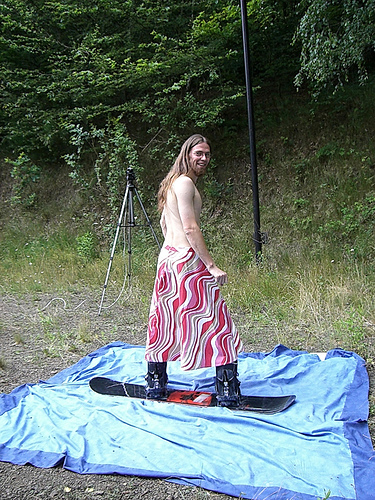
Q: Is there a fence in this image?
A: No, there are no fences.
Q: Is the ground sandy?
A: Yes, the ground is sandy.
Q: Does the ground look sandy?
A: Yes, the ground is sandy.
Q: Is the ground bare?
A: No, the ground is sandy.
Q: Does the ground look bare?
A: No, the ground is sandy.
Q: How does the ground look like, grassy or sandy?
A: The ground is sandy.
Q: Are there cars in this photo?
A: No, there are no cars.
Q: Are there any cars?
A: No, there are no cars.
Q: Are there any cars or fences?
A: No, there are no cars or fences.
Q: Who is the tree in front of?
A: The tree is in front of the man.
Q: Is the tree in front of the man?
A: Yes, the tree is in front of the man.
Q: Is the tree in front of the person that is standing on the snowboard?
A: Yes, the tree is in front of the man.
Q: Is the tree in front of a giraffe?
A: No, the tree is in front of the man.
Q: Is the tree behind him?
A: No, the tree is in front of the man.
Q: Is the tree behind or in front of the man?
A: The tree is in front of the man.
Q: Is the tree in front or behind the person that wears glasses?
A: The tree is in front of the man.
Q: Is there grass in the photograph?
A: Yes, there is grass.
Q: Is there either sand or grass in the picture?
A: Yes, there is grass.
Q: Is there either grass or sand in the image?
A: Yes, there is grass.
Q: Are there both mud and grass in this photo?
A: No, there is grass but no mud.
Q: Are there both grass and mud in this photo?
A: No, there is grass but no mud.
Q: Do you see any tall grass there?
A: Yes, there is tall grass.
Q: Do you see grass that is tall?
A: Yes, there is grass that is tall.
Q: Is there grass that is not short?
A: Yes, there is tall grass.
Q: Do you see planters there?
A: No, there are no planters.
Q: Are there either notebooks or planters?
A: No, there are no planters or notebooks.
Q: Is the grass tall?
A: Yes, the grass is tall.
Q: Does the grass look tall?
A: Yes, the grass is tall.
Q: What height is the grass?
A: The grass is tall.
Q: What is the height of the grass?
A: The grass is tall.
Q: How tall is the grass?
A: The grass is tall.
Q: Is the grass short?
A: No, the grass is tall.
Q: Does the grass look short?
A: No, the grass is tall.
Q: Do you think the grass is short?
A: No, the grass is tall.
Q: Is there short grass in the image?
A: No, there is grass but it is tall.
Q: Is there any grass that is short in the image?
A: No, there is grass but it is tall.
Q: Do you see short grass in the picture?
A: No, there is grass but it is tall.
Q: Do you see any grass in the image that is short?
A: No, there is grass but it is tall.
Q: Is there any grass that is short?
A: No, there is grass but it is tall.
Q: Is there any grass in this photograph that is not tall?
A: No, there is grass but it is tall.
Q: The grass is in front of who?
A: The grass is in front of the man.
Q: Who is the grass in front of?
A: The grass is in front of the man.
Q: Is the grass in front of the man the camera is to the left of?
A: Yes, the grass is in front of the man.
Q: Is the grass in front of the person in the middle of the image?
A: Yes, the grass is in front of the man.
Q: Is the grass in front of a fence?
A: No, the grass is in front of the man.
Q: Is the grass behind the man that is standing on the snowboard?
A: No, the grass is in front of the man.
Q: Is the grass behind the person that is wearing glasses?
A: No, the grass is in front of the man.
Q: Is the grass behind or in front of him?
A: The grass is in front of the man.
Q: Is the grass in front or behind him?
A: The grass is in front of the man.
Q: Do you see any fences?
A: No, there are no fences.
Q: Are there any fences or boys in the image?
A: No, there are no fences or boys.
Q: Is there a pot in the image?
A: No, there are no pots.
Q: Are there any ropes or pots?
A: No, there are no pots or ropes.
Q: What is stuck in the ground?
A: The pole is stuck in the ground.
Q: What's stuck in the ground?
A: The pole is stuck in the ground.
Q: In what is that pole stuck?
A: The pole is stuck in the ground.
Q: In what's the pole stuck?
A: The pole is stuck in the ground.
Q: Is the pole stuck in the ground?
A: Yes, the pole is stuck in the ground.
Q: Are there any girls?
A: No, there are no girls.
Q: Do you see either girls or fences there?
A: No, there are no girls or fences.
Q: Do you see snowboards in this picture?
A: Yes, there is a snowboard.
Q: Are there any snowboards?
A: Yes, there is a snowboard.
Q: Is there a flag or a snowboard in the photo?
A: Yes, there is a snowboard.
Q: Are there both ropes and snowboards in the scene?
A: No, there is a snowboard but no ropes.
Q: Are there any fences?
A: No, there are no fences.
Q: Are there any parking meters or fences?
A: No, there are no fences or parking meters.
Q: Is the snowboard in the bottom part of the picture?
A: Yes, the snowboard is in the bottom of the image.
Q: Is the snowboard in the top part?
A: No, the snowboard is in the bottom of the image.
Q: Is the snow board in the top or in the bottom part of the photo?
A: The snow board is in the bottom of the image.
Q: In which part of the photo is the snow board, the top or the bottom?
A: The snow board is in the bottom of the image.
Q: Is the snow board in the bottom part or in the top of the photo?
A: The snow board is in the bottom of the image.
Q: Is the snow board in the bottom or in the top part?
A: The snow board is in the bottom of the image.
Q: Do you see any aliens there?
A: No, there are no aliens.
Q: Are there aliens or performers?
A: No, there are no aliens or performers.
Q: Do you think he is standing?
A: Yes, the man is standing.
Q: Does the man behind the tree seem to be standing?
A: Yes, the man is standing.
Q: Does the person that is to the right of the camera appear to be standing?
A: Yes, the man is standing.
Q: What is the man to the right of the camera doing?
A: The man is standing.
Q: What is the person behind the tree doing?
A: The man is standing.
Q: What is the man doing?
A: The man is standing.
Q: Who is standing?
A: The man is standing.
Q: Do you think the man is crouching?
A: No, the man is standing.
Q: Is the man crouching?
A: No, the man is standing.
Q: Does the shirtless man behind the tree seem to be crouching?
A: No, the man is standing.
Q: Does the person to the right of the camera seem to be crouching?
A: No, the man is standing.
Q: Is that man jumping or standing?
A: The man is standing.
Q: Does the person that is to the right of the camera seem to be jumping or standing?
A: The man is standing.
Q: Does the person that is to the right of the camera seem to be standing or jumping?
A: The man is standing.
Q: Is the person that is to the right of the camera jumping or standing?
A: The man is standing.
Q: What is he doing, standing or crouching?
A: The man is standing.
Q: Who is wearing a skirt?
A: The man is wearing a skirt.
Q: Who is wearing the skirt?
A: The man is wearing a skirt.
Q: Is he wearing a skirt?
A: Yes, the man is wearing a skirt.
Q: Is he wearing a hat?
A: No, the man is wearing a skirt.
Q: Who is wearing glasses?
A: The man is wearing glasses.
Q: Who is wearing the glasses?
A: The man is wearing glasses.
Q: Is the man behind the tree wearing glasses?
A: Yes, the man is wearing glasses.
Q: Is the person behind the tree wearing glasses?
A: Yes, the man is wearing glasses.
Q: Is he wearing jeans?
A: No, the man is wearing glasses.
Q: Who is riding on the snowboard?
A: The man is riding on the snow board.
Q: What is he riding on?
A: The man is riding on the snow board.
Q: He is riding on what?
A: The man is riding on the snow board.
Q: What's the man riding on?
A: The man is riding on the snow board.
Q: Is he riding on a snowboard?
A: Yes, the man is riding on a snowboard.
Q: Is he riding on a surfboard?
A: No, the man is riding on a snowboard.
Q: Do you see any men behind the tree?
A: Yes, there is a man behind the tree.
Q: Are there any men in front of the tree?
A: No, the man is behind the tree.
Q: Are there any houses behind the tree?
A: No, there is a man behind the tree.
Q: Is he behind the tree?
A: Yes, the man is behind the tree.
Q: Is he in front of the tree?
A: No, the man is behind the tree.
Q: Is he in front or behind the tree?
A: The man is behind the tree.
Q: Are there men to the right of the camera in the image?
A: Yes, there is a man to the right of the camera.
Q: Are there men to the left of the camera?
A: No, the man is to the right of the camera.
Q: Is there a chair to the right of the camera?
A: No, there is a man to the right of the camera.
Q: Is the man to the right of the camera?
A: Yes, the man is to the right of the camera.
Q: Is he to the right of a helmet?
A: No, the man is to the right of the camera.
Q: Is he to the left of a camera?
A: No, the man is to the right of a camera.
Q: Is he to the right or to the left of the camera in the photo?
A: The man is to the right of the camera.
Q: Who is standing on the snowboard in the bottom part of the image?
A: The man is standing on the snowboard.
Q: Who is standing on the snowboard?
A: The man is standing on the snowboard.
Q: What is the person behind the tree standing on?
A: The man is standing on the snowboard.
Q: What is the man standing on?
A: The man is standing on the snowboard.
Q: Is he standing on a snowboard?
A: Yes, the man is standing on a snowboard.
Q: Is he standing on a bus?
A: No, the man is standing on a snowboard.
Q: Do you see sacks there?
A: No, there are no sacks.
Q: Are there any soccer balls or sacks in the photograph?
A: No, there are no sacks or soccer balls.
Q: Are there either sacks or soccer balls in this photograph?
A: No, there are no sacks or soccer balls.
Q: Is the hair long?
A: Yes, the hair is long.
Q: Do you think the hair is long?
A: Yes, the hair is long.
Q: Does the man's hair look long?
A: Yes, the hair is long.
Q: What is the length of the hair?
A: The hair is long.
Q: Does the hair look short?
A: No, the hair is long.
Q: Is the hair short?
A: No, the hair is long.